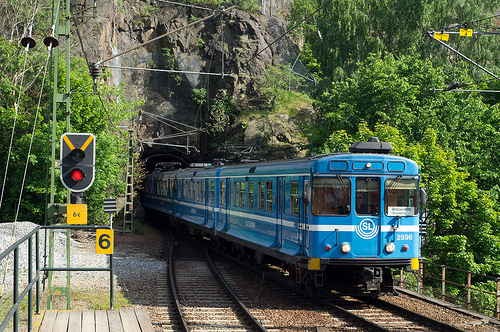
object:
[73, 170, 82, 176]
red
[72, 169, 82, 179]
light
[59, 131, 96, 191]
sign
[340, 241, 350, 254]
light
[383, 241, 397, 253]
light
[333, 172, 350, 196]
windshield wipers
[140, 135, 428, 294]
train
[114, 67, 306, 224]
cave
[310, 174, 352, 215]
windshield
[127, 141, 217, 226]
tunnel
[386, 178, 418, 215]
window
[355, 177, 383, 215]
window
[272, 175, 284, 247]
door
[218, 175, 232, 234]
door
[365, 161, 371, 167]
headlight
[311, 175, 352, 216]
windows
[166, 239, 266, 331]
tracks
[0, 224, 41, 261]
rails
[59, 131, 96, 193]
traffic light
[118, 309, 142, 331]
planks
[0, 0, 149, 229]
trees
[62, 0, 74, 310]
post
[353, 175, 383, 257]
door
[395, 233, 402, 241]
number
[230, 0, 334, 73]
power lines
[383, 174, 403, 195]
wipers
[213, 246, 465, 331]
railroad tracks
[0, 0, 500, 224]
mountain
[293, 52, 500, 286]
trees